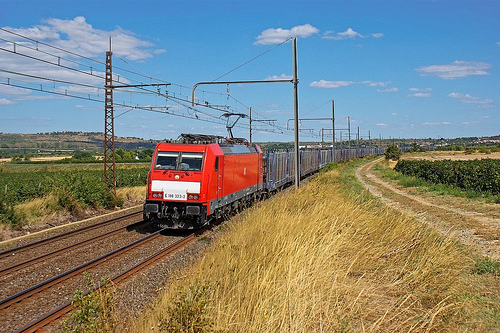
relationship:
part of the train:
[144, 140, 202, 228] [131, 130, 405, 223]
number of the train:
[161, 191, 190, 198] [147, 142, 407, 224]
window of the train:
[156, 150, 199, 170] [135, 117, 383, 234]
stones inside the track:
[105, 250, 125, 276] [38, 235, 148, 287]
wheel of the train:
[189, 225, 216, 235] [153, 143, 280, 230]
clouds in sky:
[237, 16, 395, 66] [2, 2, 483, 142]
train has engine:
[139, 129, 384, 239] [140, 130, 267, 230]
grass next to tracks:
[176, 182, 433, 329] [3, 229, 184, 331]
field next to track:
[2, 158, 161, 203] [6, 229, 193, 331]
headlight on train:
[146, 189, 165, 200] [138, 138, 385, 233]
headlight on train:
[181, 193, 202, 202] [138, 138, 385, 233]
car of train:
[137, 140, 267, 232] [139, 129, 384, 239]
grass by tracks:
[201, 175, 433, 331] [3, 229, 184, 331]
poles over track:
[186, 34, 305, 194] [0, 232, 182, 332]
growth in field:
[394, 155, 484, 190] [207, 148, 484, 331]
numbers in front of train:
[165, 190, 188, 200] [139, 129, 384, 239]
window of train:
[155, 150, 203, 171] [138, 138, 385, 233]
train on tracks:
[139, 129, 384, 239] [3, 229, 184, 331]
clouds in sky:
[2, 0, 496, 141] [6, 14, 487, 135]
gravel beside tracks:
[1, 184, 259, 331] [4, 194, 214, 330]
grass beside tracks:
[117, 140, 498, 327] [4, 194, 214, 330]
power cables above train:
[12, 20, 366, 149] [141, 151, 351, 240]